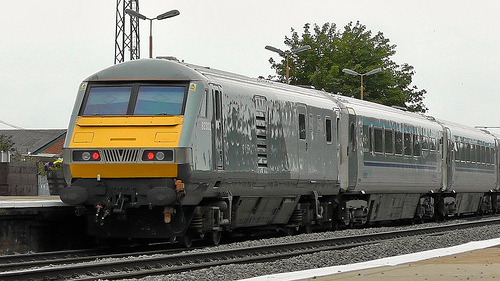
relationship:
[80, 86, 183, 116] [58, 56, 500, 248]
front windows of engine car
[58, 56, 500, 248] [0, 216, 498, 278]
engine car on tracks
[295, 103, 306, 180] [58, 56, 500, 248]
door of engine car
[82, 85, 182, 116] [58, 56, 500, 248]
windshield of engine car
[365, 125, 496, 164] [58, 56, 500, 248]
window on engine car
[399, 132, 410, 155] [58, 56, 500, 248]
window of engine car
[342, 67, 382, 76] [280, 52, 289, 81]
lights on post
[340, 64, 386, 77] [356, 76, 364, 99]
lights on post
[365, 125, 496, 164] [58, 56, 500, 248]
window of engine car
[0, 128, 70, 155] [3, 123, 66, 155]
roof of building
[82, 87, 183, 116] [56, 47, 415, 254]
windshield of train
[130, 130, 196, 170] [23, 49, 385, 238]
light on train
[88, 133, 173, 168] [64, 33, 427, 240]
signals on train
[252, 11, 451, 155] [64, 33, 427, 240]
trees behind train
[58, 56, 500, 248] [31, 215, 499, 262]
engine car on ground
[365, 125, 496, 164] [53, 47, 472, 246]
window on train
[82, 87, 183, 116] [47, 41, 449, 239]
windshield on train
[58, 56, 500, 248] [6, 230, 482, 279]
engine car on tracks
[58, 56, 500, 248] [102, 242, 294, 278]
engine car on tracks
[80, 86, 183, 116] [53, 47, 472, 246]
front windows in train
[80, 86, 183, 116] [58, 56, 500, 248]
front windows in engine car